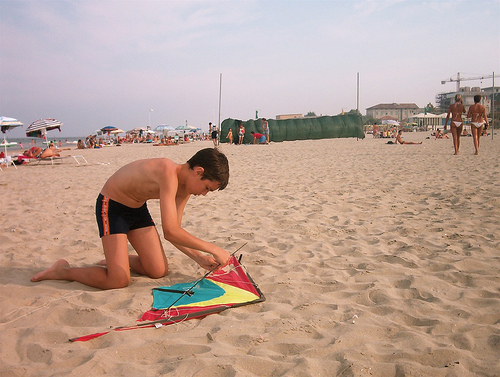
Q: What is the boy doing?
A: Fixing a kite.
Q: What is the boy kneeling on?
A: Sand.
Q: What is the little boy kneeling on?
A: Sand.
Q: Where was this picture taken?
A: Beach.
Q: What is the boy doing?
A: Fixing kite.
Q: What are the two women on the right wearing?
A: White bikinis.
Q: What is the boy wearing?
A: Bathing suit.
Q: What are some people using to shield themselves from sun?
A: Beach umbrellas.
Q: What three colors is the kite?
A: Red, yellow and blue.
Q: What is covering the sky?
A: Clouds.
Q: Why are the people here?
A: To enjoy the beach.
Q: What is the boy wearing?
A: Swim trunks.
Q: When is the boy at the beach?
A: Daytime.